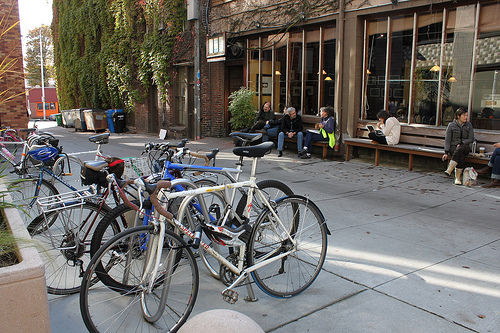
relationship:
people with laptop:
[366, 108, 403, 147] [364, 123, 381, 133]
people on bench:
[256, 99, 279, 146] [265, 109, 341, 158]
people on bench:
[276, 104, 303, 157] [265, 109, 341, 158]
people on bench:
[305, 101, 340, 155] [265, 109, 341, 158]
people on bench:
[366, 106, 404, 146] [348, 103, 499, 163]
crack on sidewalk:
[326, 245, 423, 316] [302, 158, 494, 325]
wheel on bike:
[234, 195, 339, 309] [80, 137, 331, 329]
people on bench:
[366, 108, 403, 147] [338, 113, 499, 175]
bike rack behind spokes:
[138, 227, 180, 323] [92, 242, 194, 331]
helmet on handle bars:
[19, 145, 66, 166] [27, 141, 66, 175]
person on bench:
[443, 108, 475, 183] [343, 118, 484, 173]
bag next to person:
[464, 155, 483, 197] [443, 93, 475, 195]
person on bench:
[443, 93, 475, 195] [392, 115, 451, 167]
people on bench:
[252, 100, 279, 143] [254, 112, 334, 154]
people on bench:
[276, 104, 303, 157] [254, 112, 334, 154]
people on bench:
[305, 101, 340, 155] [254, 112, 334, 154]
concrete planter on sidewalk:
[0, 175, 52, 331] [4, 122, 499, 332]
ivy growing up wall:
[50, 3, 190, 108] [48, 2, 227, 135]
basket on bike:
[120, 155, 167, 192] [77, 163, 345, 321]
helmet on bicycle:
[19, 145, 66, 166] [21, 144, 113, 216]